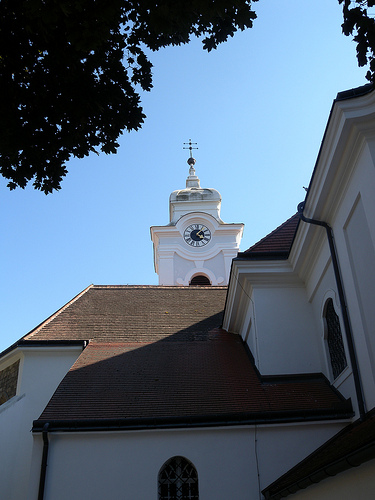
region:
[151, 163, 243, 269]
large outside clock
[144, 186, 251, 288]
clock with gold arms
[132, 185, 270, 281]
clock at the top of the building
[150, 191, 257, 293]
clock on a white building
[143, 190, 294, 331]
clock is above the main building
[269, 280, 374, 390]
shaped windows on the building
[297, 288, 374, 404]
a metal gate over the windows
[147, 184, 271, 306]
clock is on a tower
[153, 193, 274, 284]
clock is located on the tower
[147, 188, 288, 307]
outside clock is white and black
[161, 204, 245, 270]
clock has roman numerals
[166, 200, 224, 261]
hands of the clock are gold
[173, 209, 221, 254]
time appears to be 4:07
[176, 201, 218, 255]
clock center is black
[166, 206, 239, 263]
roman numerals are black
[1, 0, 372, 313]
Sky is clear and sunny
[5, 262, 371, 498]
building is white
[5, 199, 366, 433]
roofs are reddish brown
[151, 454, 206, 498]
window is surrounded by iron bars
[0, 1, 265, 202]
large tree above the left side of the building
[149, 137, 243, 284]
tall white church steeple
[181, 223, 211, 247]
black roman numeral clock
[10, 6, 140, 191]
deciduous tree branch with green leaves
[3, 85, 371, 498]
large white church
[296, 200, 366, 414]
black water drain pipe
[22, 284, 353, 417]
brown shingled roof top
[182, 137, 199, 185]
black and white steeple top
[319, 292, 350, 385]
church window with rounded top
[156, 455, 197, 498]
white window with black bars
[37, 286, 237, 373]
shadow on church from sun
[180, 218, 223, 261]
circular clock on tower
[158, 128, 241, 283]
white tower of a building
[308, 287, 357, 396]
window on the side of the building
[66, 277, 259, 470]
brown roof of a white building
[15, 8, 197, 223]
blue sky and tree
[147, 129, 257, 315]
white tower with a clock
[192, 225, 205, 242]
gold colored hands of a clock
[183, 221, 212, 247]
circular clock with black center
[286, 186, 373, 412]
black storm drain gutter on side of building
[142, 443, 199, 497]
bars in window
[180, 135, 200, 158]
a weather vane on the tower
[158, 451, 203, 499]
a window on the building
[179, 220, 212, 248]
a clock on the tower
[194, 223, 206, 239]
the gold hands on a clock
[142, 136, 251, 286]
a white tower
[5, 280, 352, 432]
the roof of the building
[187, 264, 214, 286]
a window on the tower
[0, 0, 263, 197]
a tree near the church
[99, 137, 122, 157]
a leaf on the tree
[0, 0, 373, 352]
a clear blue sky